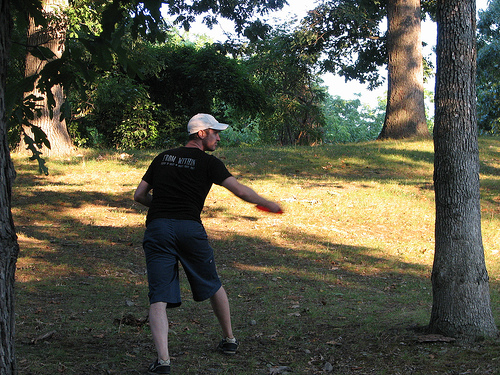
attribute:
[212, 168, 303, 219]
arm — man's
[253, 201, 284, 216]
frisbee — red 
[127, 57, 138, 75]
leaf — green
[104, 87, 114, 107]
leaf — green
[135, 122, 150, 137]
leaf — green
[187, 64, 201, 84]
leaf — green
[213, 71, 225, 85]
leaf — green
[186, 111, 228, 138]
hat — white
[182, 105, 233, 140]
cap — white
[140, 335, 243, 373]
sneakers — dark 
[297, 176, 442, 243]
sunny area — sunny 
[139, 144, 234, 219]
shirt — black 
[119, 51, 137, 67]
leaf — green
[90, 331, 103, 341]
leaves — dried , scattered 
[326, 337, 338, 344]
leaves — scattered , dried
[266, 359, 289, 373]
leaves — scattered , dried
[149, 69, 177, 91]
leaf — green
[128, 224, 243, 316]
grey shorts — gray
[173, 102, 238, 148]
hat. — white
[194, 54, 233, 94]
leaf — green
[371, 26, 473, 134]
trunk — sun dappled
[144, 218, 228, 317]
shorts — knee length, navy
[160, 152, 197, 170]
print — white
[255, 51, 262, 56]
leaf — green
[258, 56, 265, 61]
leaf — green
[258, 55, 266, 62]
leaf — green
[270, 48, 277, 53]
leaf — green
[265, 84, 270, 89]
leaf — green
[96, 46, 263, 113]
shrub — large , green 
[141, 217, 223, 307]
shorts — blue 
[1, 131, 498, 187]
green grass — green 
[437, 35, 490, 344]
tree trunk — tall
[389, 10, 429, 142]
tree trunk — tall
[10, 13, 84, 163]
tree trunk — tall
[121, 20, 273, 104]
leaves — green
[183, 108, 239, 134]
hat — white 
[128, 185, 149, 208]
elbow — man's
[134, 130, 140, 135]
leaf — green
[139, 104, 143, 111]
leaf — green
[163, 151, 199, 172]
writing — white